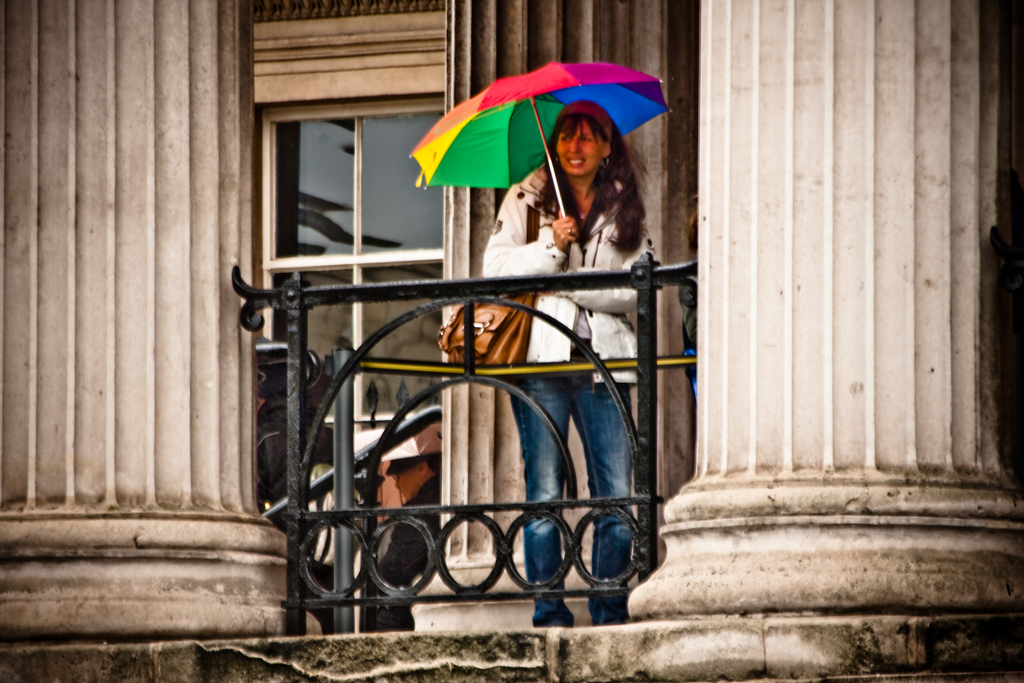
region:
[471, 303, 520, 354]
the purse is brown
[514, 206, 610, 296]
the coat is white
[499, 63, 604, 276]
she is carrying an umbrella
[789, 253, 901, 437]
the pillar is white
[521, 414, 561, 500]
the jeans are blue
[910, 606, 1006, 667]
the stone has moss on it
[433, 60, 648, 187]
the umbrella is colorful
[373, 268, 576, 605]
the gate is black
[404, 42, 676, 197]
fabric on an umbrella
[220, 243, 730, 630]
iron fence near a woman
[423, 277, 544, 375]
brown bag on a woman's side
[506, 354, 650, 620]
jeans worn by a woman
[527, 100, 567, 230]
silver handle of an umbrella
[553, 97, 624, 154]
headband on a woman's head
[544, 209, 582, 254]
hand holding an umbrella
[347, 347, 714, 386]
yellow and black rope near a woman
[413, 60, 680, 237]
Multicolored umbrella over head.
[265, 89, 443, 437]
Window with four panes.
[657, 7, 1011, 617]
Large column on right.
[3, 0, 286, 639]
Large column on the left.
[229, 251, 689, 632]
Black iron fence.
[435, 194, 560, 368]
Brown over the shoulder handbag.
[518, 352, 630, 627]
Pair of blue jeans.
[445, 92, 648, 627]
Woman wearing white jacket and blue jeans.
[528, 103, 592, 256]
Long silver umbrella pole.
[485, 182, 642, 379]
A white long sleeved jacket.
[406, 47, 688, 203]
multi colored umbrella held by the woman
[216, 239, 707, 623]
wrought iron fence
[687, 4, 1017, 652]
column on the left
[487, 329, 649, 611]
jeans on the woman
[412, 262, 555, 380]
brown purse the woman is carrying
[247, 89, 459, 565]
window of the building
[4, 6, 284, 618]
column on the lefy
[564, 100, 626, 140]
headband on the woman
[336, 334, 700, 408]
yellow and black rope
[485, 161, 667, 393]
white jacket on the lady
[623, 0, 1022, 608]
a white Dorian column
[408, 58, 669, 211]
a multicolored umbrella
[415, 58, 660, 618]
a woman holding an umbrella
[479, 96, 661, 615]
woman wearing a headband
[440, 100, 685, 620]
woman carrying a purse on her shoulder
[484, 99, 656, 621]
woman wearing a white coat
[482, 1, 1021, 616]
woman standing next to a column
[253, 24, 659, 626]
woman standing next to a window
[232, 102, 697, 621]
woman standing behind a black metal fence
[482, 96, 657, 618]
woman wearing old blue jeans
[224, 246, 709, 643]
black rail in between columns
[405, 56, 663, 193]
rainbow colored umbrella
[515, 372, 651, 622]
bright blue faded blue jeans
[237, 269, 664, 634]
black metal fence by woman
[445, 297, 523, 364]
camel brown hand bag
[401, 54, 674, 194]
brightly colored umbrella top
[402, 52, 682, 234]
the multi colored umbrella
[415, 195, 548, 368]
the handbag is brown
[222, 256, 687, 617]
the railing is wrought iron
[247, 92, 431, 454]
the window behind the woman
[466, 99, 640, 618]
the woman is smiling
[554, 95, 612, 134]
the headband on the woman's head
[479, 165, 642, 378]
the jacket is white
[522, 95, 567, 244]
the handle of the umbrella is metal